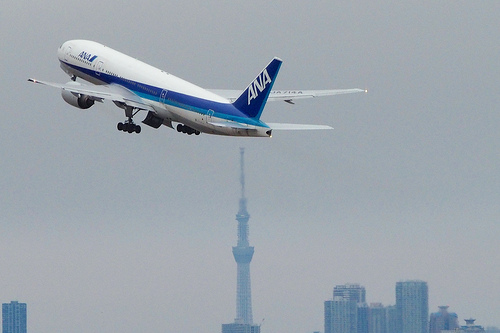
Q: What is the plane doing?
A: The plane is flying.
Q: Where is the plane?
A: It is flying in the air.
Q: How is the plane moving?
A: It is flying.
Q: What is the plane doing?
A: It is in the air flying away.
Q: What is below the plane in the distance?
A: Those are a tower and some buildings.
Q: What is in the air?
A: Air plane.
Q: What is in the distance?
A: Buildings.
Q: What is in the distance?
A: Tower and buildings.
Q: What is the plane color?
A: White and blue.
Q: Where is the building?
A: In the distance.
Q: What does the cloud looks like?
A: Cloudy.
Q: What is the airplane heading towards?
A: The sky.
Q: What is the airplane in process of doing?
A: Taking off.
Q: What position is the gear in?
A: Down.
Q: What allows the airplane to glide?
A: Wings.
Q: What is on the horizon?
A: Buildings.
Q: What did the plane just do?
A: Took off.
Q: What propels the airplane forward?
A: Enginges.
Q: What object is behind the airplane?
A: A tower.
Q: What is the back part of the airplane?
A: The tail.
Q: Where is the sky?
A: Behind the plane.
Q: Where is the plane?
A: In the sky.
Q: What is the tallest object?
A: Spire of the building.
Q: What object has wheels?
A: The plane.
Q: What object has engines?
A: The plane.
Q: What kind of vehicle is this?
A: Airplane.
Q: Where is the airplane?
A: In the sky.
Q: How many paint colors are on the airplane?
A: Three.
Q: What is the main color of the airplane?
A: White.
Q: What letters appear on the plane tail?
A: ANA.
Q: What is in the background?
A: Buildings.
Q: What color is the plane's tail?
A: Dark blue.